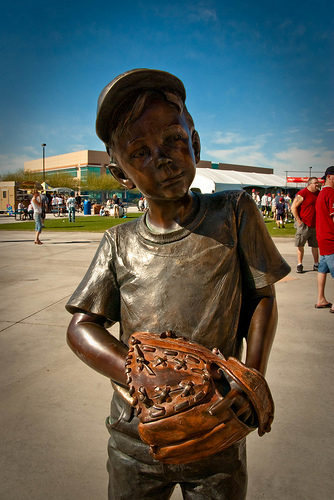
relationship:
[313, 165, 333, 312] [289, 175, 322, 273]
man standing behind a man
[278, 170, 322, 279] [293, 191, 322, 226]
man in red shirt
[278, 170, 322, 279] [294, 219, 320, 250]
man in gray shorts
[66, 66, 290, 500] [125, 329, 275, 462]
boy statue with a glove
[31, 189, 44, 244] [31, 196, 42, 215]
person in shirt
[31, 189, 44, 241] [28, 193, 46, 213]
person walking with shirt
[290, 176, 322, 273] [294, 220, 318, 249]
man wearing shorts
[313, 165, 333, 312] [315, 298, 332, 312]
man wearing brown sandals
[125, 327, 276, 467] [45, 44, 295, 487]
glove on statue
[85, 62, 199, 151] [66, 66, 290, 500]
hat on boy statue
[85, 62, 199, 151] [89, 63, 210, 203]
hat on head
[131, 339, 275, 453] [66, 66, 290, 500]
ball on boy statue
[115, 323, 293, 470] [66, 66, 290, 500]
glove on boy statue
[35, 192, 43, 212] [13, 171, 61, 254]
crossed arms on woman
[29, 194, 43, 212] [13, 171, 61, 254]
shirt on woman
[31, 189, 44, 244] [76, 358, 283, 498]
person wearing jeans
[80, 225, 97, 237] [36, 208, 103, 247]
grass in field